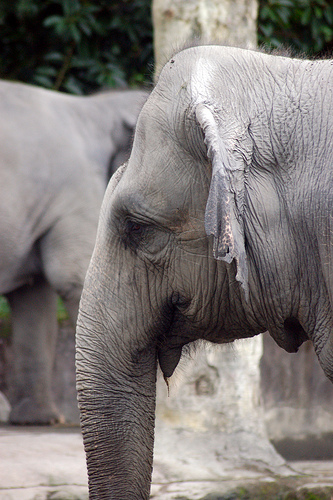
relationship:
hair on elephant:
[145, 23, 330, 86] [75, 44, 330, 500]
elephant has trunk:
[75, 44, 330, 500] [76, 238, 159, 500]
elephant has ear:
[75, 44, 330, 500] [179, 97, 248, 296]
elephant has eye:
[75, 44, 330, 500] [129, 217, 140, 232]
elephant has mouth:
[75, 44, 330, 500] [147, 295, 185, 377]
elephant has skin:
[75, 44, 330, 500] [128, 46, 332, 380]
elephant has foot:
[1, 76, 151, 424] [9, 279, 64, 425]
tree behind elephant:
[150, 1, 298, 476] [75, 44, 330, 500]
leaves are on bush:
[260, 3, 332, 55] [1, 4, 332, 58]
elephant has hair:
[75, 44, 330, 500] [145, 23, 330, 86]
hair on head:
[145, 23, 330, 86] [103, 44, 332, 196]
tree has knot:
[150, 1, 298, 476] [195, 372, 216, 397]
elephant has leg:
[1, 76, 151, 424] [9, 279, 64, 425]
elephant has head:
[75, 44, 330, 500] [103, 44, 332, 196]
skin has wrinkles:
[128, 46, 332, 380] [163, 36, 298, 374]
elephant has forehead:
[75, 44, 330, 500] [114, 43, 213, 174]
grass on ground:
[209, 484, 331, 500] [5, 424, 332, 500]